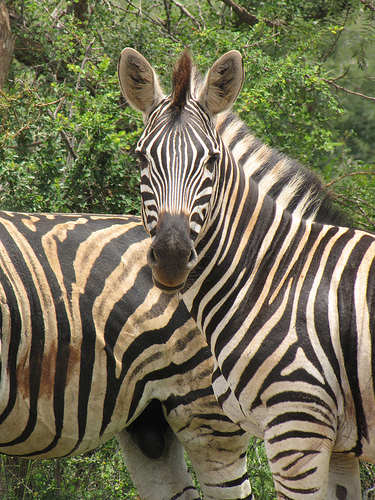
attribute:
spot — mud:
[5, 341, 82, 404]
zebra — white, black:
[1, 206, 255, 498]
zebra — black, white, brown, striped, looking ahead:
[114, 43, 362, 498]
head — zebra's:
[116, 42, 246, 294]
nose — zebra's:
[144, 236, 200, 274]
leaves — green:
[35, 99, 90, 171]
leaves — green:
[2, 82, 50, 136]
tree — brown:
[172, 17, 347, 167]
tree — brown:
[135, 22, 349, 162]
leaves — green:
[281, 115, 338, 160]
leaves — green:
[301, 21, 346, 51]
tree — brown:
[123, 17, 349, 159]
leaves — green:
[0, 69, 51, 116]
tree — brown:
[2, 2, 143, 215]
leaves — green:
[26, 87, 74, 144]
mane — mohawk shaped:
[164, 47, 198, 126]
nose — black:
[135, 203, 196, 293]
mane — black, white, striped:
[205, 104, 362, 269]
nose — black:
[127, 221, 219, 307]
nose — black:
[141, 210, 215, 317]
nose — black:
[135, 207, 207, 301]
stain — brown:
[12, 330, 91, 406]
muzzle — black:
[142, 213, 198, 300]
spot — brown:
[5, 338, 87, 400]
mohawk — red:
[169, 47, 221, 124]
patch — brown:
[12, 340, 80, 401]